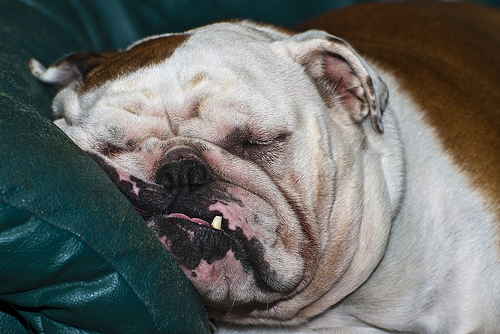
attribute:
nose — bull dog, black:
[39, 36, 499, 328]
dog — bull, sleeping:
[58, 32, 490, 324]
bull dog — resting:
[27, 16, 498, 333]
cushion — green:
[4, 1, 174, 332]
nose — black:
[151, 153, 213, 200]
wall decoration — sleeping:
[55, 24, 386, 269]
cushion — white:
[0, 14, 227, 332]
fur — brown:
[408, 43, 468, 99]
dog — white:
[85, 34, 496, 312]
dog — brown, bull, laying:
[27, 0, 499, 333]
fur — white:
[394, 196, 495, 318]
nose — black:
[129, 119, 276, 271]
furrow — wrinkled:
[99, 62, 226, 147]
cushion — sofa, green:
[0, 0, 353, 330]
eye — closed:
[233, 128, 295, 165]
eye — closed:
[98, 137, 136, 157]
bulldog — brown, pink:
[28, 23, 498, 330]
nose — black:
[135, 141, 242, 213]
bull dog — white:
[34, 5, 494, 310]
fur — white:
[369, 60, 484, 301]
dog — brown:
[24, 4, 464, 319]